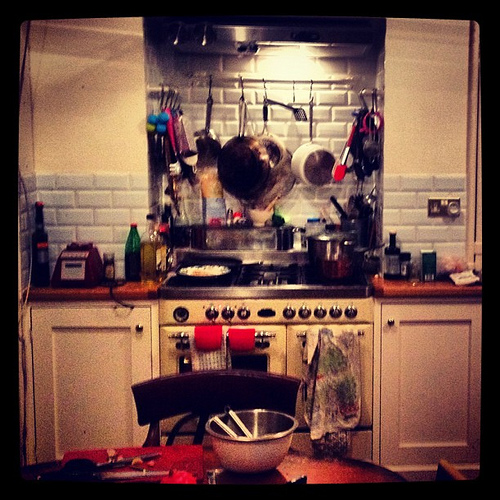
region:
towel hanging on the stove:
[298, 332, 370, 457]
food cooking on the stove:
[179, 259, 236, 291]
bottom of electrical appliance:
[48, 232, 108, 291]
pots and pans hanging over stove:
[189, 85, 339, 195]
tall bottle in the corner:
[28, 205, 52, 293]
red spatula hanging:
[333, 107, 343, 191]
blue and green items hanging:
[140, 92, 178, 137]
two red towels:
[178, 329, 263, 349]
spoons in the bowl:
[216, 415, 258, 442]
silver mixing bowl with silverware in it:
[202, 405, 294, 475]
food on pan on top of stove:
[171, 256, 248, 288]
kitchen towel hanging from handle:
[298, 327, 371, 440]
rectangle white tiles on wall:
[30, 168, 148, 249]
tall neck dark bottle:
[32, 197, 54, 284]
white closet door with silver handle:
[371, 300, 476, 468]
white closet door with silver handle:
[26, 300, 152, 450]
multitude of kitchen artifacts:
[146, 79, 383, 206]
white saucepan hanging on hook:
[292, 76, 340, 193]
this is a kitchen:
[37, 30, 486, 479]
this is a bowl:
[183, 393, 318, 463]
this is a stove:
[153, 207, 387, 316]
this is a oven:
[133, 300, 397, 435]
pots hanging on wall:
[155, 54, 393, 221]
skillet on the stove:
[171, 232, 240, 300]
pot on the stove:
[303, 200, 363, 295]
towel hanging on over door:
[276, 324, 379, 465]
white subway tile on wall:
[389, 173, 463, 260]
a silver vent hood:
[168, 17, 383, 92]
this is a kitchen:
[2, 3, 499, 495]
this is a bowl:
[202, 403, 299, 474]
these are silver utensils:
[209, 405, 252, 437]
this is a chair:
[129, 369, 305, 431]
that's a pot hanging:
[190, 72, 221, 174]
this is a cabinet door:
[377, 300, 491, 476]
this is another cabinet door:
[25, 303, 160, 468]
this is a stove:
[156, 224, 374, 465]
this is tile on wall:
[17, 175, 165, 292]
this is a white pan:
[289, 85, 337, 192]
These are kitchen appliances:
[131, 70, 414, 300]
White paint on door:
[398, 320, 465, 444]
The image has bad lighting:
[19, 13, 491, 493]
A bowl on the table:
[181, 385, 329, 485]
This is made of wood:
[306, 455, 377, 492]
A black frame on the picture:
[6, 5, 498, 490]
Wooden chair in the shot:
[109, 356, 335, 453]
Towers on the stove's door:
[145, 289, 405, 460]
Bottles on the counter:
[21, 188, 174, 290]